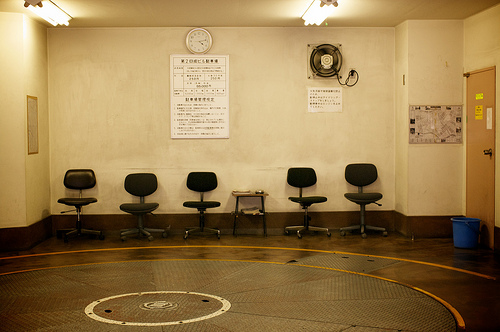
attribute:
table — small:
[227, 186, 272, 236]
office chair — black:
[48, 163, 105, 243]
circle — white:
[83, 286, 232, 325]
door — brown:
[459, 63, 495, 254]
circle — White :
[77, 284, 234, 330]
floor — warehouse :
[5, 238, 498, 328]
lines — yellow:
[81, 234, 305, 269]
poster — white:
[168, 51, 230, 140]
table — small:
[226, 184, 271, 242]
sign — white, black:
[300, 79, 353, 112]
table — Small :
[232, 190, 270, 236]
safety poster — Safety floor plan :
[405, 103, 465, 145]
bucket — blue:
[450, 212, 482, 249]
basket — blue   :
[442, 210, 483, 248]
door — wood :
[463, 64, 496, 248]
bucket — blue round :
[449, 210, 484, 254]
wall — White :
[47, 30, 169, 164]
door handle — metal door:
[482, 145, 492, 162]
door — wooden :
[464, 67, 499, 227]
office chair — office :
[345, 160, 385, 237]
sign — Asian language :
[167, 48, 232, 140]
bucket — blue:
[449, 207, 493, 255]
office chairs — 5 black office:
[56, 160, 394, 240]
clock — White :
[168, 30, 218, 55]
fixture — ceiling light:
[302, 2, 347, 29]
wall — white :
[45, 25, 395, 232]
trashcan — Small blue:
[419, 207, 493, 271]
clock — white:
[186, 25, 211, 54]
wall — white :
[389, 77, 465, 164]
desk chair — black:
[114, 170, 172, 246]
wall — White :
[58, 32, 398, 213]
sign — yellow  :
[474, 97, 483, 99]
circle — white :
[84, 281, 235, 329]